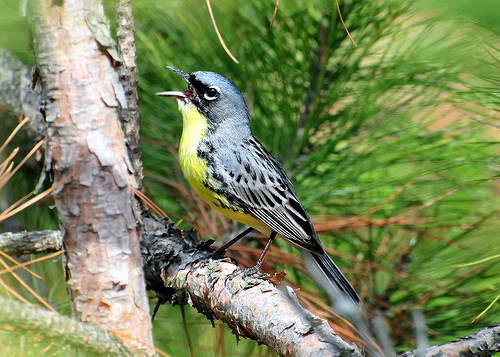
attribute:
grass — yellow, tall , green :
[307, 109, 498, 259]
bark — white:
[87, 7, 142, 219]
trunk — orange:
[26, 0, 159, 352]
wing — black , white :
[196, 136, 403, 257]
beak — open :
[145, 57, 194, 102]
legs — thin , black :
[190, 225, 278, 282]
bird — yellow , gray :
[150, 55, 323, 304]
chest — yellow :
[178, 120, 243, 211]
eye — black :
[201, 77, 228, 110]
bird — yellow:
[156, 61, 374, 327]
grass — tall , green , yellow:
[366, 47, 493, 278]